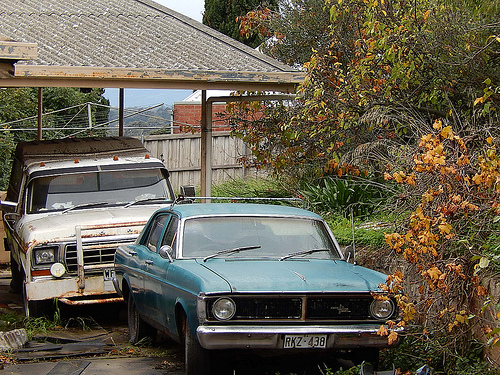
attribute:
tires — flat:
[14, 250, 44, 320]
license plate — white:
[280, 333, 328, 351]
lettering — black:
[284, 335, 301, 347]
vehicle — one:
[1, 137, 181, 326]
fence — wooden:
[134, 128, 307, 195]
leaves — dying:
[418, 186, 461, 270]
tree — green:
[2, 87, 111, 189]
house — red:
[170, 40, 307, 135]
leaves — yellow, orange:
[373, 119, 498, 347]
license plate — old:
[283, 335, 327, 349]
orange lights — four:
[43, 154, 151, 165]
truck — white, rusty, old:
[3, 136, 194, 323]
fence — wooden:
[141, 132, 307, 199]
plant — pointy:
[297, 175, 370, 217]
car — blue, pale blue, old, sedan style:
[113, 202, 407, 370]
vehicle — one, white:
[3, 139, 196, 319]